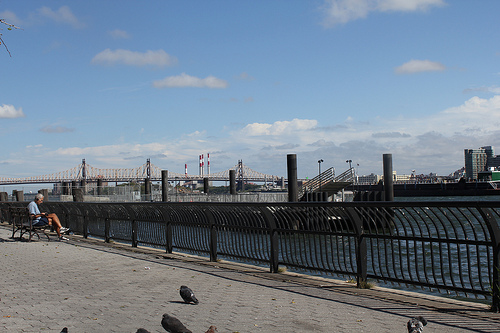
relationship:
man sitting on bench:
[24, 191, 63, 241] [9, 197, 28, 240]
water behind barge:
[416, 190, 488, 218] [0, 181, 499, 312]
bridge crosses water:
[11, 178, 63, 189] [416, 190, 488, 218]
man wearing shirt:
[24, 191, 63, 241] [23, 194, 37, 216]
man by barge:
[24, 191, 63, 241] [0, 181, 499, 312]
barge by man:
[0, 181, 499, 312] [24, 191, 63, 241]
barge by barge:
[109, 181, 341, 236] [0, 181, 499, 312]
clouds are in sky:
[103, 53, 218, 111] [207, 41, 241, 73]